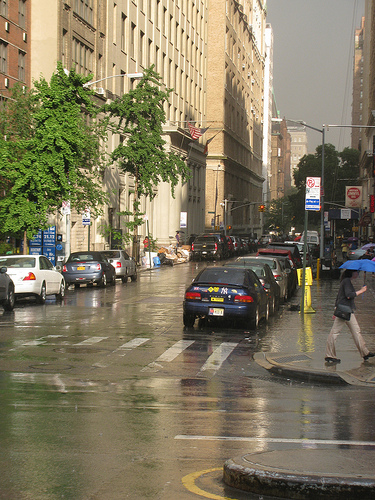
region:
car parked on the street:
[176, 262, 274, 337]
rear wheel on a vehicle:
[35, 278, 50, 304]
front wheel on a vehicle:
[55, 276, 67, 300]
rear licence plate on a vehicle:
[205, 304, 225, 319]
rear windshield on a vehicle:
[193, 266, 249, 288]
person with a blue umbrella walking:
[321, 256, 374, 369]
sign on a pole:
[300, 170, 326, 216]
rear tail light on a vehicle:
[230, 290, 257, 306]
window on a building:
[14, 41, 29, 89]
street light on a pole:
[115, 64, 151, 84]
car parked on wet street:
[183, 268, 268, 328]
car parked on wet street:
[236, 261, 277, 304]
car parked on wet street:
[242, 257, 290, 291]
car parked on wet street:
[0, 253, 65, 297]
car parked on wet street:
[65, 250, 115, 288]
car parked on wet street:
[101, 248, 136, 278]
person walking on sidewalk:
[325, 265, 372, 361]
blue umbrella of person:
[340, 256, 372, 271]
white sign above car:
[306, 175, 321, 211]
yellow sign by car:
[294, 268, 314, 314]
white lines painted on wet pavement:
[27, 323, 248, 379]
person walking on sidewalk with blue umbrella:
[323, 248, 371, 368]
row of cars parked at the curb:
[188, 239, 305, 332]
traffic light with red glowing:
[256, 201, 266, 216]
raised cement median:
[214, 435, 351, 497]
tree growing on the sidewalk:
[6, 168, 84, 244]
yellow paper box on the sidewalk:
[293, 265, 316, 314]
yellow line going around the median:
[180, 458, 212, 494]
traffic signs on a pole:
[300, 169, 324, 232]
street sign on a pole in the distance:
[203, 208, 216, 216]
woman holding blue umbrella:
[329, 251, 373, 309]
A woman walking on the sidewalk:
[313, 249, 372, 381]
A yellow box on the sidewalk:
[291, 262, 317, 325]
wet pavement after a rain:
[92, 344, 252, 410]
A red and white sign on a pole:
[301, 170, 322, 216]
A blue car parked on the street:
[179, 261, 274, 341]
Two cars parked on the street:
[59, 242, 142, 298]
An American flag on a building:
[179, 107, 210, 153]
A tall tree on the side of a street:
[111, 63, 175, 289]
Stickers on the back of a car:
[199, 280, 239, 310]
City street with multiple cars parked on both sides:
[4, 167, 316, 484]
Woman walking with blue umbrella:
[325, 254, 372, 373]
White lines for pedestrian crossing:
[0, 325, 238, 394]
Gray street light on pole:
[265, 106, 328, 292]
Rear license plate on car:
[207, 307, 223, 320]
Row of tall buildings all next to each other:
[5, 0, 314, 279]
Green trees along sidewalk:
[1, 57, 202, 276]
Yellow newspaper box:
[294, 263, 317, 321]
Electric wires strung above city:
[329, 0, 360, 152]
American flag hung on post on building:
[179, 113, 217, 150]